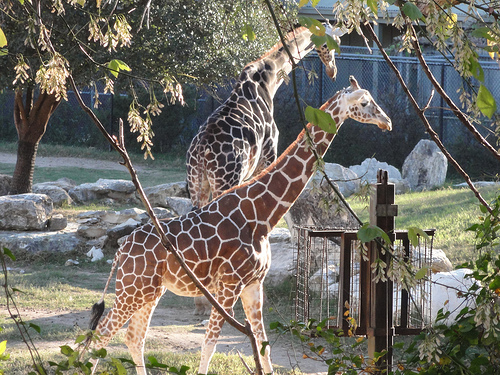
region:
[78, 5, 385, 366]
Two giraffes walking along.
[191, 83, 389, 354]
A younger looking giraffe.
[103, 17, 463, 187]
Giraffes behind enclosed fences.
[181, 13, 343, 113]
A giraffe with dark brown spots.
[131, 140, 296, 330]
A giraffe with light brown spots.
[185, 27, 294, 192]
A giraffe walking away.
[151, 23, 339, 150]
A giraffe walking towards fence.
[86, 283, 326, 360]
A giraffe walking on ground.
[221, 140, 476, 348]
A giraffe next to a cage.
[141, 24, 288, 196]
A mature giraffe.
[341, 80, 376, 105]
right ear of giraffee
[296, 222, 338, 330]
metal wire on right of photo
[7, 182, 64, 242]
large grey rock in front of tree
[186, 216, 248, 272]
brown and yellow spots on giraffee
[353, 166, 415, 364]
tall brown wooden post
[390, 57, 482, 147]
silver chain link fence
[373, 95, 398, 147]
nose on giraffee facing right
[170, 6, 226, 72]
green leaves on branches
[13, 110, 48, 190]
brown tree trunk in back of photo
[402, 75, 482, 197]
brown wooden branch on right of photo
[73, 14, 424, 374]
two giraffe's in captivity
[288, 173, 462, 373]
feeder for the giraffe's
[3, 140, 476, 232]
large rocks on the ground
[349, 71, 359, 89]
horns on the giraffe's head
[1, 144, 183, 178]
path along the ground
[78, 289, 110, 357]
hair on the end of the tail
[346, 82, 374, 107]
right ear of the giraffe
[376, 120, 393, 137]
mouth of the giraffe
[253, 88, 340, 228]
giraffe has a long neck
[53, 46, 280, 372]
branch of a tree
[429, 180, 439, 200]
part of a rock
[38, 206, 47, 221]
part of a rock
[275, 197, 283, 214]
neck of a giraffe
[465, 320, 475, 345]
part of the leaf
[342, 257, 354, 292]
part of a nail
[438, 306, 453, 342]
part of a bunch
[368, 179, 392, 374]
the post is made of wood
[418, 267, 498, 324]
the rock is white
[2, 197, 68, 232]
this rock is gray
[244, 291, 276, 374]
the giraffes leg has patches of white on it.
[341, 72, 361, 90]
the giraffi has a horn on its head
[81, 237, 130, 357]
the tip of the tail is black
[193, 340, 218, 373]
the bottom of this leg is all white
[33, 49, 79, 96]
these leaves on the tree are brown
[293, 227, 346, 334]
the wire is white and attached to wood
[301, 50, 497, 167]
a fence divides the pasture from the rest of the facility